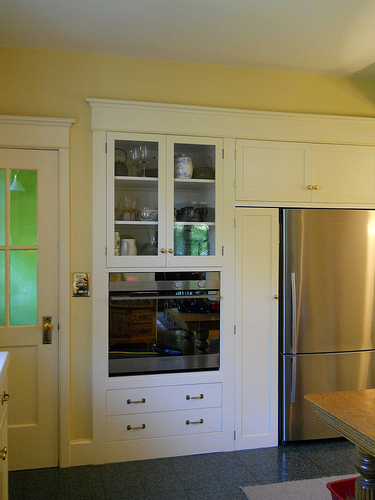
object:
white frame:
[0, 113, 76, 470]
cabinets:
[85, 96, 375, 465]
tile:
[234, 448, 279, 475]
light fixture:
[7, 171, 27, 191]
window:
[10, 170, 37, 246]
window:
[9, 249, 37, 325]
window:
[0, 248, 6, 326]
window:
[0, 168, 5, 247]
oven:
[108, 270, 220, 376]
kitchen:
[0, 0, 375, 500]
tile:
[213, 465, 259, 493]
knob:
[36, 315, 58, 346]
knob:
[312, 185, 320, 190]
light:
[73, 271, 90, 299]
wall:
[0, 44, 375, 467]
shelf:
[112, 169, 216, 187]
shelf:
[112, 215, 217, 230]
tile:
[134, 457, 177, 480]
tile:
[176, 472, 230, 500]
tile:
[245, 459, 295, 486]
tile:
[303, 447, 357, 477]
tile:
[205, 450, 245, 471]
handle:
[307, 183, 318, 189]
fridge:
[279, 208, 375, 446]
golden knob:
[160, 248, 165, 253]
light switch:
[71, 270, 89, 298]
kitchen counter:
[302, 388, 374, 499]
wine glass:
[137, 144, 152, 177]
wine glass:
[128, 145, 142, 176]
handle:
[0, 446, 8, 462]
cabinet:
[0, 351, 11, 500]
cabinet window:
[114, 139, 160, 178]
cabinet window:
[174, 142, 218, 180]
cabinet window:
[114, 178, 159, 222]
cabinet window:
[174, 181, 217, 223]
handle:
[181, 390, 206, 401]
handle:
[157, 247, 166, 256]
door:
[0, 113, 76, 474]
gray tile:
[7, 436, 365, 500]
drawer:
[105, 405, 223, 443]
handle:
[185, 416, 206, 424]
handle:
[125, 419, 146, 429]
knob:
[166, 246, 176, 254]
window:
[114, 139, 159, 257]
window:
[173, 142, 215, 256]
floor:
[7, 438, 361, 500]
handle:
[127, 398, 146, 405]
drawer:
[105, 382, 223, 417]